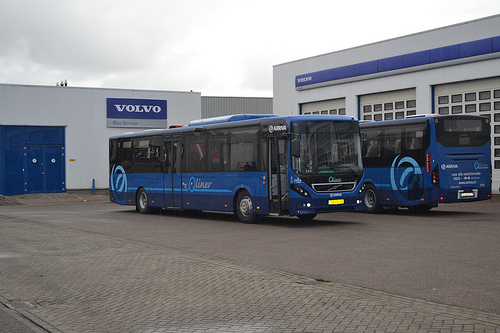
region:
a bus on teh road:
[122, 105, 372, 312]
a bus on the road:
[362, 100, 494, 269]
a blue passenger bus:
[134, 131, 414, 264]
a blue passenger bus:
[346, 98, 443, 180]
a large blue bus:
[136, 108, 381, 223]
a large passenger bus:
[125, 126, 322, 215]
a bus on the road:
[109, 95, 460, 309]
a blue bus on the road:
[134, 83, 460, 294]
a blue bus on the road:
[362, 98, 499, 212]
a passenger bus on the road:
[87, 113, 357, 220]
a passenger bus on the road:
[357, 98, 489, 208]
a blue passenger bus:
[129, 131, 324, 205]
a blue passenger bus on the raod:
[80, 97, 389, 247]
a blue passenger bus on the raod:
[348, 93, 486, 204]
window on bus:
[215, 127, 294, 166]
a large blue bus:
[356, 110, 495, 212]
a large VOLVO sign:
[105, 97, 166, 127]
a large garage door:
[299, 97, 344, 116]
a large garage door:
[358, 86, 417, 118]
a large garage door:
[431, 75, 498, 192]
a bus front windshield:
[291, 120, 363, 172]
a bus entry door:
[265, 132, 289, 214]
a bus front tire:
[233, 188, 256, 220]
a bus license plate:
[459, 190, 475, 200]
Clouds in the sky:
[31, 7, 185, 73]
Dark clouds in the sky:
[21, 3, 195, 75]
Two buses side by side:
[101, 117, 485, 235]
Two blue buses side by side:
[136, 96, 493, 228]